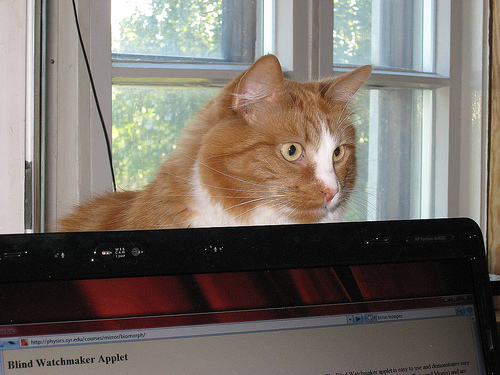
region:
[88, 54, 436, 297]
the cat is orange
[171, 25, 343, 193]
the cat is orange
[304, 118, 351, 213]
cat's nose is white and orange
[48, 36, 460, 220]
orange and white cat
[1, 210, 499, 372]
top of a laptop comuter monitor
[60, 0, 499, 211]
cat in front of white window frame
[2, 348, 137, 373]
Blind Watchmaker Applet written on screen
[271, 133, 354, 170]
cat's large eyes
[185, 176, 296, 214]
white whiskers on the cat's face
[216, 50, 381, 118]
triangular shaped cat's ears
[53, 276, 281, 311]
red and black graphic boarder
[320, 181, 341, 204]
cat's small pink nose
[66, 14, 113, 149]
black wire behind cat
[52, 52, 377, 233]
part of orange and white cat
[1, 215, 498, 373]
part of a laptop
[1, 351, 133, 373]
words on computer screen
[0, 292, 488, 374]
webpage open on computer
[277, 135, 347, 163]
cat's bright yellow eyes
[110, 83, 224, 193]
trees outside the window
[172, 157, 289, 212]
cat's long white whiskers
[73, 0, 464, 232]
white window behind cat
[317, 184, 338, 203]
cat's little pink nose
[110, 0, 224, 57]
sun shining brightly on trees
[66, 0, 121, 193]
Black cord hanging down the white wall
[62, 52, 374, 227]
Tan and white cat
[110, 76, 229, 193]
Lower Right window pane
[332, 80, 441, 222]
Window pane in the lower left corner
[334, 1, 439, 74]
Upper left window pane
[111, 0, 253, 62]
Window pane in upper right corner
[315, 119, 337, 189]
White patch on cat's face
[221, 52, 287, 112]
Right ear of cat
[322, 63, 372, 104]
Left ear of cat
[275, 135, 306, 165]
Right eye of cat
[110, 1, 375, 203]
green leavea on trees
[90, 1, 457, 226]
four panes of window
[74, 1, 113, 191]
black cord across window frame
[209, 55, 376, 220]
orange and white cat face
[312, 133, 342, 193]
white nose on cat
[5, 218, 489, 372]
top of open laptop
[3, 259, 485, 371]
image on laptop screen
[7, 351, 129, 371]
black words on screen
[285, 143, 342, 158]
black pupils in eyes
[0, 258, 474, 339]
black and red design